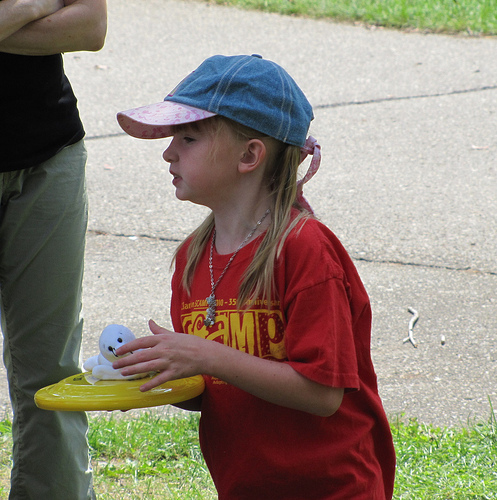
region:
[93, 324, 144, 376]
Stuffed toy in girl's hand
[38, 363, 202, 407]
Yellow plastic frisbee in girl's hand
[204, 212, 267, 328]
Necklace around girl's neck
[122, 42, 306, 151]
Blue cap with pink bill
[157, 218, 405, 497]
Red shirt on little girl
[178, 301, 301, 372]
Yellow letters on red shirt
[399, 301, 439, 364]
Gray twig on road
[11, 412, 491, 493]
Green grass beside road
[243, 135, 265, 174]
Ear on little girl's head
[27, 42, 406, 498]
Little girl holding toys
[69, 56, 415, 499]
girl wearing hat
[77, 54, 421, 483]
girl is wearing a t shirt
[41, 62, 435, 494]
girl holding a toy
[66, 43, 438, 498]
girl holding frisbee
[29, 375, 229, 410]
frisbee is yellow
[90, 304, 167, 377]
the toy is white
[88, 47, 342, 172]
the hat is pink and blue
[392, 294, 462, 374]
twig on the pavement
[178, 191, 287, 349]
necklace around the neck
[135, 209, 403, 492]
the t shirt is red and yellow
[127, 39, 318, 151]
Blue ball cap on head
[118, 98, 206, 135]
Pink rim of hat on girl's head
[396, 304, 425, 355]
Gray twig on road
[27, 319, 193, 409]
Toys in girl's hands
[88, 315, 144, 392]
White stuffed toy on frisbee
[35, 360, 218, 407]
Shiny yellow toy frisbee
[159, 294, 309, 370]
Yellow text on girl's shirt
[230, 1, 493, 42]
Strip of green grass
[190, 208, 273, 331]
Necklace on little girl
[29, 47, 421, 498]
girl wearing a hat outside with a stuffed animal on a flying disc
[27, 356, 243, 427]
a yellow flying disc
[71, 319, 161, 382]
a white stuffed animal on the yellow flying disc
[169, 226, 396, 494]
the girl is wearing a red shirt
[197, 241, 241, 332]
the girl is wearing a necklace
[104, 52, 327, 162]
pink and blue hat that the girl is wearing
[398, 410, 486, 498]
green grass the girl is standing on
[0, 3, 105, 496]
adult standing next to the girl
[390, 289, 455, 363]
stick laying on the pavement behind the girl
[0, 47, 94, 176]
the adult is wearing a black shirt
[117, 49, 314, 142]
a blue jean cap with a pink visor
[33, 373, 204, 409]
a yellow Frisbee disk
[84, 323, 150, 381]
a white face on a toy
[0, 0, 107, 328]
an adult standing on the side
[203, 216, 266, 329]
the girl is wearing a necklace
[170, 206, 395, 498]
the girl is wearing a red t-shirt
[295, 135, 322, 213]
a pink strap on the cap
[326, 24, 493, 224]
a cement sidewalk behind the little girl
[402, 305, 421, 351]
a broken tree branch twig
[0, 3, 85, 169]
the person standing is wearing a black shirt